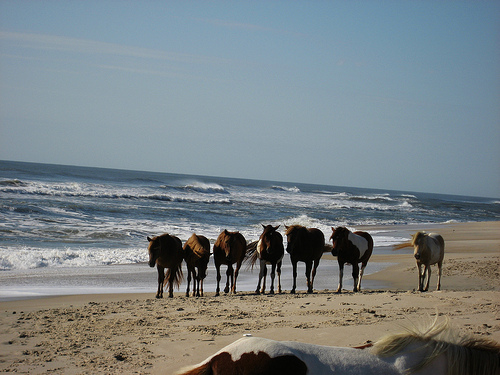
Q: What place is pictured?
A: It is an ocean.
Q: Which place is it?
A: It is an ocean.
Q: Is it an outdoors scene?
A: Yes, it is outdoors.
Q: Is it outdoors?
A: Yes, it is outdoors.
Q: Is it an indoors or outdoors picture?
A: It is outdoors.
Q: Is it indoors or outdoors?
A: It is outdoors.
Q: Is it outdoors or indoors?
A: It is outdoors.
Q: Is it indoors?
A: No, it is outdoors.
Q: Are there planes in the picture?
A: No, there are no planes.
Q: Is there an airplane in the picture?
A: No, there are no airplanes.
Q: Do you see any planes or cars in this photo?
A: No, there are no planes or cars.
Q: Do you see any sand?
A: Yes, there is sand.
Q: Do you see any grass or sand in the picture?
A: Yes, there is sand.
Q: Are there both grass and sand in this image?
A: No, there is sand but no grass.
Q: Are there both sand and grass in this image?
A: No, there is sand but no grass.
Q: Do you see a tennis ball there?
A: No, there are no tennis balls.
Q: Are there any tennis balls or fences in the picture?
A: No, there are no tennis balls or fences.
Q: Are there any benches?
A: No, there are no benches.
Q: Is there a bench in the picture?
A: No, there are no benches.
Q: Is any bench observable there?
A: No, there are no benches.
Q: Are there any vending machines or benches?
A: No, there are no benches or vending machines.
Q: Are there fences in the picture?
A: No, there are no fences.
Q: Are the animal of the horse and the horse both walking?
A: Yes, both the animal and the horse are walking.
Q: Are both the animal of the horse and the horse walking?
A: Yes, both the animal and the horse are walking.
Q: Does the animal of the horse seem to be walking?
A: Yes, the animal is walking.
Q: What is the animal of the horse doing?
A: The animal is walking.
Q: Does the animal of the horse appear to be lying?
A: No, the animal is walking.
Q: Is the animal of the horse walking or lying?
A: The animal is walking.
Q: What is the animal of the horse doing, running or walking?
A: The animal is walking.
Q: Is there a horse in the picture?
A: Yes, there is a horse.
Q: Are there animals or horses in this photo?
A: Yes, there is a horse.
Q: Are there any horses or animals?
A: Yes, there is a horse.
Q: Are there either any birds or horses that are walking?
A: Yes, the horse is walking.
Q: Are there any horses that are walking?
A: Yes, there is a horse that is walking.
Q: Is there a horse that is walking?
A: Yes, there is a horse that is walking.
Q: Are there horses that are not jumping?
A: Yes, there is a horse that is walking.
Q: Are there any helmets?
A: No, there are no helmets.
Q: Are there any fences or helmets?
A: No, there are no helmets or fences.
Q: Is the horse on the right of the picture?
A: Yes, the horse is on the right of the image.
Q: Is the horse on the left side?
A: No, the horse is on the right of the image.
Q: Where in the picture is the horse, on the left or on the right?
A: The horse is on the right of the image.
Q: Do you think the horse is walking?
A: Yes, the horse is walking.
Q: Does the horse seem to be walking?
A: Yes, the horse is walking.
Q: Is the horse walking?
A: Yes, the horse is walking.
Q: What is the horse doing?
A: The horse is walking.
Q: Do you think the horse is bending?
A: No, the horse is walking.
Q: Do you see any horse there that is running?
A: No, there is a horse but it is walking.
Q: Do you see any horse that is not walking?
A: No, there is a horse but it is walking.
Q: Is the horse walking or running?
A: The horse is walking.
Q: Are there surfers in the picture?
A: No, there are no surfers.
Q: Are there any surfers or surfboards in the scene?
A: No, there are no surfers or surfboards.